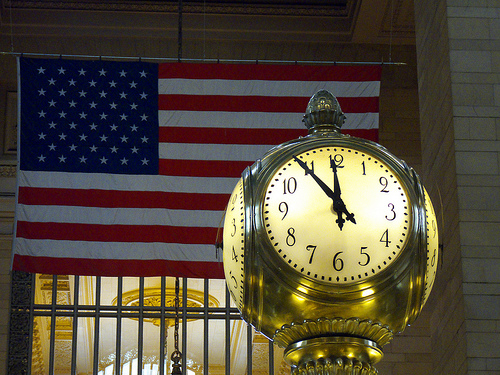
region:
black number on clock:
[327, 147, 345, 169]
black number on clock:
[358, 154, 377, 181]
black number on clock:
[373, 171, 399, 199]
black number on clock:
[371, 228, 408, 261]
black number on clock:
[374, 173, 393, 190]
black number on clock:
[354, 237, 386, 289]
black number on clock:
[329, 253, 356, 280]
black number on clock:
[301, 233, 321, 273]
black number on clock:
[282, 227, 302, 254]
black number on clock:
[271, 191, 287, 228]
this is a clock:
[242, 132, 427, 373]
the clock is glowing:
[228, 115, 436, 367]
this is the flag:
[19, 61, 212, 263]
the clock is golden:
[297, 293, 388, 355]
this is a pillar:
[442, 22, 491, 94]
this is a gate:
[40, 287, 207, 372]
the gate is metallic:
[64, 291, 203, 366]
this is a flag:
[56, 69, 210, 220]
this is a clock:
[271, 154, 401, 281]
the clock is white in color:
[299, 195, 325, 230]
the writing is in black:
[285, 215, 302, 255]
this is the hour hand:
[322, 158, 350, 216]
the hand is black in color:
[331, 159, 350, 213]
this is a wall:
[433, 23, 497, 175]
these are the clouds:
[89, 76, 151, 144]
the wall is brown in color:
[436, 22, 483, 117]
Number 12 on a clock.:
[328, 152, 347, 171]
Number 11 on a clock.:
[301, 159, 318, 178]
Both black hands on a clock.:
[290, 153, 358, 229]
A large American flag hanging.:
[12, 52, 382, 289]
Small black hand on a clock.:
[328, 155, 345, 229]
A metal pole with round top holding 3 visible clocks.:
[221, 88, 441, 374]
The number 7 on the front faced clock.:
[306, 244, 317, 266]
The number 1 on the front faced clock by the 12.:
[359, 160, 369, 177]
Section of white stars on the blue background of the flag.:
[34, 62, 149, 167]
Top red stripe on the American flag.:
[155, 59, 385, 85]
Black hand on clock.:
[296, 153, 328, 205]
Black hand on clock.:
[318, 158, 355, 222]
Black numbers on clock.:
[260, 155, 400, 263]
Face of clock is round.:
[283, 152, 405, 275]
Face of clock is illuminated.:
[276, 167, 394, 258]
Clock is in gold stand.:
[250, 164, 399, 317]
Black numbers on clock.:
[211, 212, 256, 279]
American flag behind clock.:
[33, 75, 294, 223]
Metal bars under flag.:
[53, 281, 178, 341]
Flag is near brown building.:
[392, 106, 457, 208]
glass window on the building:
[76, 272, 96, 307]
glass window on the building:
[96, 275, 118, 310]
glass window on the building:
[120, 270, 140, 307]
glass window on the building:
[143, 276, 158, 304]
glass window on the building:
[165, 275, 182, 307]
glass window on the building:
[186, 276, 201, 308]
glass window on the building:
[208, 276, 227, 306]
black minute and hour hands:
[290, 152, 357, 229]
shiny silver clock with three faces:
[220, 87, 438, 374]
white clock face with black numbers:
[262, 143, 413, 285]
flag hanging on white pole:
[2, 50, 409, 281]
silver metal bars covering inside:
[26, 268, 292, 374]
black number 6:
[330, 248, 345, 273]